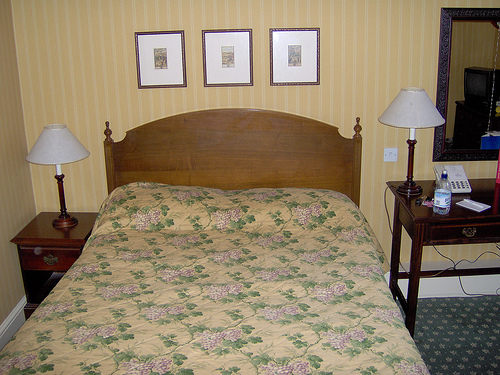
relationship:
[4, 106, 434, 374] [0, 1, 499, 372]
bed in bedroom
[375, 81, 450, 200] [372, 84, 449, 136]
lamp has a shade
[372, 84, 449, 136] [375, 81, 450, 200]
shade on lamp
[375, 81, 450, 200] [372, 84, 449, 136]
lamp has shade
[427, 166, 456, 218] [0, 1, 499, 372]
bottle in bedroom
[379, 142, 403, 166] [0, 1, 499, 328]
light switch on wall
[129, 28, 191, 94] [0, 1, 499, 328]
picture on wall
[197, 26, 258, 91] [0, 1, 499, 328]
picture on wall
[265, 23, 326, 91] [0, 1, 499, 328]
picture on wall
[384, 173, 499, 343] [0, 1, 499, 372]
table in bedroom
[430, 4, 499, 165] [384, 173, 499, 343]
mirror over table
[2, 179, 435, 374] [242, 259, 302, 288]
cover has pink flowers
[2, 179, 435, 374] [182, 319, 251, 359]
cover has pink flower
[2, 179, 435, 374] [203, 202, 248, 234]
cover has pink flower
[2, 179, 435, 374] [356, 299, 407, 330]
cover has pink flower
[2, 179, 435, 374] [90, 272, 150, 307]
cover has pink flower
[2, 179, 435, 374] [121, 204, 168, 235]
cover has pink flower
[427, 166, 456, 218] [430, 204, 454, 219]
bottle has water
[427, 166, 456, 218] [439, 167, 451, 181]
bottle has sport top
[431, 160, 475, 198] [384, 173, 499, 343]
telephone on table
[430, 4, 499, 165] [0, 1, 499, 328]
mirror on wall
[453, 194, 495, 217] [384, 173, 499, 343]
paper on table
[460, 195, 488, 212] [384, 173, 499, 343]
pen on table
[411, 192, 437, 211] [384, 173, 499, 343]
keys are on table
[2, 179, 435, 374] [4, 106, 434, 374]
cover on bed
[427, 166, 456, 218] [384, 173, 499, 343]
bottle on table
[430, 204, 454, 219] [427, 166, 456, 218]
water in bottle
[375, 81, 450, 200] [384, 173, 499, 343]
lamp on table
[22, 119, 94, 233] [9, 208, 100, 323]
lamp on night stand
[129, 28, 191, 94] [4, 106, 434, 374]
picture above bed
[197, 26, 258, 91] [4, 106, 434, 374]
picture above bed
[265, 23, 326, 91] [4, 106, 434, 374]
picture above bed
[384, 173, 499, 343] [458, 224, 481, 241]
table has handle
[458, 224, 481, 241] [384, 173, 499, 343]
handle on table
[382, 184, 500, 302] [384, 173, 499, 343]
cord under table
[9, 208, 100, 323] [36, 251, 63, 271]
night stand has handle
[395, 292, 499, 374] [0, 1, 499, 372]
floor in bedroom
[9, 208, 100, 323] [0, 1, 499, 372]
night stand in bedroom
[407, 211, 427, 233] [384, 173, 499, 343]
edge on table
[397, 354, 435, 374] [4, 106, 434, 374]
edge on bed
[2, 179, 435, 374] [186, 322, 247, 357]
cover has flower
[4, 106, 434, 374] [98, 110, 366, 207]
bed has headboard